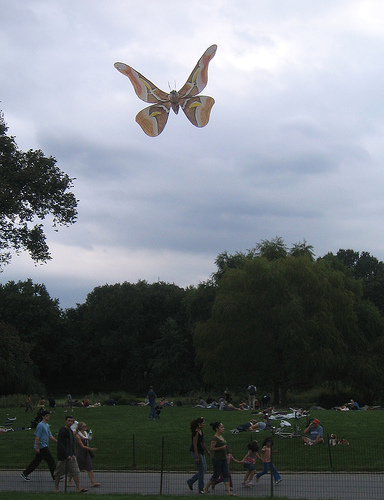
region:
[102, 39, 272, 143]
A giant moth kite in the sky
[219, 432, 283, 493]
Little girls holding hands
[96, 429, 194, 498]
A fence lines the path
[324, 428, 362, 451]
A dog rests in the grass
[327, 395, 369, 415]
Resting under the trees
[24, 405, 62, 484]
A man in a blue shirt is taking large strides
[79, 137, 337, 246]
The sky is filled with large puffy clouds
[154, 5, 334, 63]
The sun shines through the clouds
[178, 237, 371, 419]
A full green leafy tree provides shade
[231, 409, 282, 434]
Laying in the grass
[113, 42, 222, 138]
A kite in the sky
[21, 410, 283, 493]
People walking on the road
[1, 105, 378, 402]
Trees in the park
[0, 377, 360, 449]
People playing on grass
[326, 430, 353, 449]
Dog laying on the grass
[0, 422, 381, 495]
Black metal fence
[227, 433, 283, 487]
Kids playing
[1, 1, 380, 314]
Gray cloudy sky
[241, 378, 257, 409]
Man wearing backpack standing under a tree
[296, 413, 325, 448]
Man talking on cellphone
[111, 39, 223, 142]
The giant butterfly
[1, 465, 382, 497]
The grey walkway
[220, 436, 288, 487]
The children holding hands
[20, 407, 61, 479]
Man with blue shirt and black pants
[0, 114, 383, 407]
Trees in the background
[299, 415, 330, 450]
Man with the red hat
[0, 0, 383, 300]
The cloudy sky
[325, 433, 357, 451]
The dog lying on the grass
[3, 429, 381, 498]
The fences along the path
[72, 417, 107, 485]
The woman with a white ring on her neck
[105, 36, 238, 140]
orange, white and yellow butterfly kite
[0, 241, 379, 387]
green tree line in background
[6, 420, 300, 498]
black fencing along sidewalk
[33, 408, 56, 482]
man in blue shirt and jeans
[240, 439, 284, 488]
two young children in orange shirts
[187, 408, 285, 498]
two women walking with children on sidewalk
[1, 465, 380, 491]
grey concrete sidewalk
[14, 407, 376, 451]
green park lawn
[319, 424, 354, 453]
brown and white dog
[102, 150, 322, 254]
grey clouds in sky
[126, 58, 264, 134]
A butterfly in the sky.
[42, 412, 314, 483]
People are walking on the sidewalk.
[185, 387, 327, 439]
People are laying on the grass.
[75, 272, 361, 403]
The trees are green and big.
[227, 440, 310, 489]
Kids holding hands as they walk.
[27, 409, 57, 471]
The boy has on a blue shirt.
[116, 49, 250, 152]
The butterfly in the sky is colorful.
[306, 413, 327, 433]
The man is wearing a red cap.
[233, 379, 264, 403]
the boy has on a backpack.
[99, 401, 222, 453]
The grass is green.